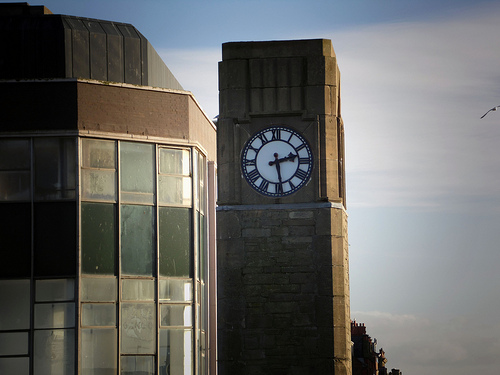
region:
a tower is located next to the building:
[181, 32, 371, 344]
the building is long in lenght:
[38, 22, 236, 374]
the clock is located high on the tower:
[236, 116, 317, 222]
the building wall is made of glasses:
[88, 137, 204, 373]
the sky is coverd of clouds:
[391, 124, 496, 281]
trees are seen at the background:
[350, 289, 398, 374]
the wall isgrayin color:
[47, 12, 135, 99]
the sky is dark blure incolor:
[402, 217, 472, 307]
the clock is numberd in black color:
[256, 132, 295, 190]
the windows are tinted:
[58, 199, 218, 286]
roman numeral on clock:
[267, 125, 282, 142]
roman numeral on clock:
[283, 130, 295, 144]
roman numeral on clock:
[292, 143, 308, 155]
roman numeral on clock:
[295, 153, 310, 168]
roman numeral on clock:
[291, 164, 310, 181]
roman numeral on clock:
[288, 179, 300, 193]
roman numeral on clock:
[272, 180, 287, 192]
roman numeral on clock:
[258, 177, 269, 191]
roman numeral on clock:
[245, 167, 262, 182]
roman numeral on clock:
[243, 155, 260, 170]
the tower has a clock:
[241, 128, 313, 200]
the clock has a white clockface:
[245, 126, 313, 195]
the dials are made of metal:
[265, 150, 296, 186]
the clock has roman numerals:
[242, 130, 310, 197]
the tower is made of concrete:
[216, 38, 355, 370]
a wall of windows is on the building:
[14, 125, 206, 371]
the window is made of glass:
[120, 144, 153, 202]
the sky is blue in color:
[36, 3, 496, 371]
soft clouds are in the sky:
[153, 15, 498, 248]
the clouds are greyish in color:
[156, 22, 498, 210]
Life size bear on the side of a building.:
[459, 331, 473, 365]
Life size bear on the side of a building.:
[370, 265, 401, 370]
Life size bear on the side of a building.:
[269, 338, 284, 363]